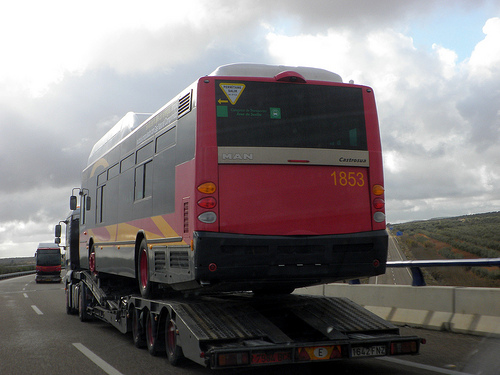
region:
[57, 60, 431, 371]
Bus on a tow truck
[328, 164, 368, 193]
Number 1853 on a bus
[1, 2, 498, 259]
Big white clouds in the sky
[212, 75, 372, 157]
Window on back of a bus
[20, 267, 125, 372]
White lines on the road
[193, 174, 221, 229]
Three rear lights on bus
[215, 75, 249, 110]
A triangle shaped sign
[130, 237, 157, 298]
A round black tire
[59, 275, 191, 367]
Wheels on a tow truck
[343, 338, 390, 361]
A white license plate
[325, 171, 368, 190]
yellow numbers on the back of a bus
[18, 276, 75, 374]
white lines on the highway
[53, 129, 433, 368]
flat bed of a tow truck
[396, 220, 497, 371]
cement barrier on the highway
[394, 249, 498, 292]
metal guardail on the highway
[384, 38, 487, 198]
big white billowy clouds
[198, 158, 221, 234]
tail and break lights on a bus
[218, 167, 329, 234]
red back of a bus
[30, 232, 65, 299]
back of a bus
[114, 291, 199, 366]
three tires on a flat bed trailer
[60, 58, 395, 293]
black and red bus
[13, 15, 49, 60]
white clouds in blue sky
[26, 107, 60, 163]
white clouds in blue sky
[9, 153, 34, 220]
white clouds in blue sky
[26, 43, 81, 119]
white clouds in blue sky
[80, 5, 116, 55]
white clouds in blue sky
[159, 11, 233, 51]
white clouds in blue sky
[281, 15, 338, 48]
white clouds in blue sky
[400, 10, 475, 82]
white clouds in blue sky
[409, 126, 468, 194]
white clouds in blue sky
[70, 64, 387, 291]
a bus on a flat bed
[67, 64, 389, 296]
a bus being transported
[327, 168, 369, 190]
an identification number on a bus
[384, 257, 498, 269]
a rail beside the highway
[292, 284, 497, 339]
concrete barriers adjacent to the highway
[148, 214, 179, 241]
a yellow strip on the bus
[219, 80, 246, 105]
a triangular sign on the bus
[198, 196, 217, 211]
tail light on the back of the bus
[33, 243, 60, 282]
a truck in front of the closest truck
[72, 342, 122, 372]
a line in the highway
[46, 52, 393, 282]
A red and black bus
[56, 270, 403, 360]
A large black trailer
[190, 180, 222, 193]
Yellow lights on back of bus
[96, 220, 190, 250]
Red and yellow design on side of bus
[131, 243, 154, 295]
Black tire with red rim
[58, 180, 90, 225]
Side mirror on bus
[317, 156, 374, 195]
Yellow numbers on right side back of bus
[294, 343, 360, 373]
Yellow license plate on truck trailer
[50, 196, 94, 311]
Black semi tractor trailer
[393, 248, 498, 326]
Metal rail on overpass bridge